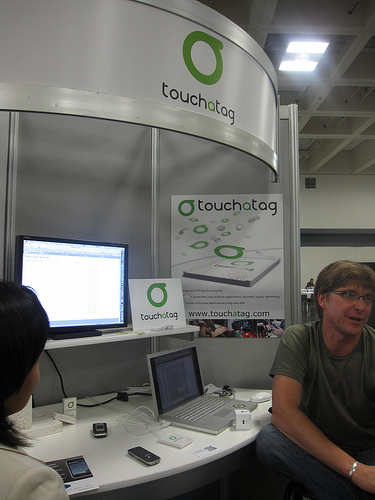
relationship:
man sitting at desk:
[255, 260, 375, 497] [6, 382, 281, 498]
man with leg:
[255, 260, 375, 497] [258, 423, 372, 499]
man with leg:
[255, 260, 375, 497] [285, 460, 332, 499]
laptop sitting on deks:
[142, 341, 262, 439] [34, 392, 258, 469]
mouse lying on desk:
[246, 381, 279, 416] [31, 361, 285, 498]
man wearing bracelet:
[254, 257, 375, 499] [346, 446, 369, 496]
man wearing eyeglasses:
[255, 260, 375, 497] [333, 282, 373, 307]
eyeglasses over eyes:
[333, 282, 373, 307] [348, 289, 372, 301]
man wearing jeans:
[254, 257, 375, 499] [259, 429, 342, 498]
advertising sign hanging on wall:
[171, 192, 285, 319] [0, 109, 291, 407]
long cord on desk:
[41, 348, 68, 399] [37, 382, 128, 483]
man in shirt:
[255, 260, 375, 497] [263, 317, 363, 443]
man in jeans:
[255, 260, 375, 497] [247, 418, 356, 492]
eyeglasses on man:
[331, 287, 375, 303] [255, 260, 375, 497]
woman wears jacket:
[12, 258, 73, 497] [3, 436, 66, 491]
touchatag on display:
[157, 77, 242, 124] [2, 3, 295, 494]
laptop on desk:
[142, 341, 262, 439] [96, 390, 277, 483]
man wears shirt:
[254, 257, 375, 499] [269, 318, 373, 444]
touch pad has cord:
[154, 429, 192, 451] [133, 403, 161, 435]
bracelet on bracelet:
[348, 461, 358, 480] [348, 460, 359, 480]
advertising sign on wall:
[171, 192, 285, 321] [5, 90, 256, 333]